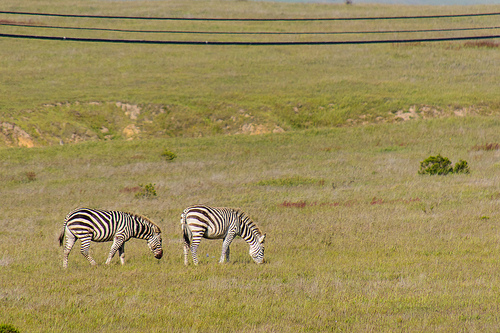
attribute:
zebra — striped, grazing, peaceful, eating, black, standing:
[165, 199, 276, 272]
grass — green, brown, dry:
[297, 157, 335, 179]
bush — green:
[428, 134, 466, 183]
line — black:
[249, 12, 310, 63]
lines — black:
[325, 14, 405, 71]